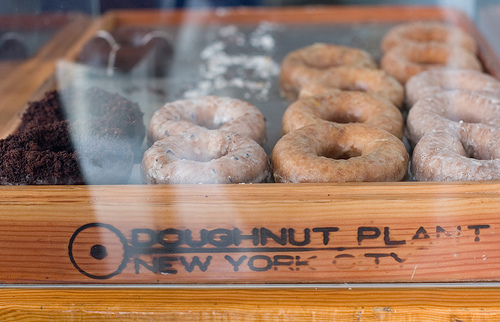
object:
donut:
[15, 87, 146, 158]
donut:
[270, 122, 410, 182]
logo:
[65, 221, 489, 280]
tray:
[2, 9, 498, 283]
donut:
[408, 122, 498, 182]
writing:
[355, 226, 382, 247]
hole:
[180, 153, 228, 163]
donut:
[141, 130, 269, 185]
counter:
[2, 286, 498, 320]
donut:
[0, 117, 133, 184]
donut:
[405, 90, 499, 147]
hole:
[318, 144, 363, 161]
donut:
[67, 222, 129, 281]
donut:
[280, 90, 402, 142]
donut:
[300, 64, 404, 107]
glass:
[1, 0, 498, 287]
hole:
[324, 110, 364, 124]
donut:
[149, 95, 268, 151]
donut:
[379, 41, 482, 84]